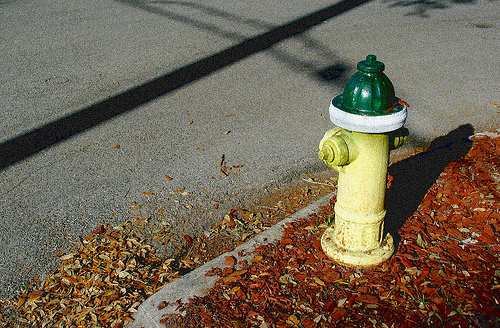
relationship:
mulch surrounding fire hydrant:
[0, 113, 500, 328] [310, 52, 416, 273]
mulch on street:
[4, 200, 260, 326] [7, 30, 309, 245]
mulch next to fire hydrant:
[0, 113, 500, 328] [310, 52, 416, 273]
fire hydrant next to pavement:
[303, 42, 409, 272] [0, 1, 500, 328]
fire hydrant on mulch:
[317, 55, 409, 270] [404, 134, 498, 326]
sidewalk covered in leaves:
[17, 15, 482, 304] [24, 134, 493, 327]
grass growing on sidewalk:
[413, 290, 431, 310] [125, 123, 497, 326]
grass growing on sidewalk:
[441, 296, 453, 307] [125, 123, 497, 326]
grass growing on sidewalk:
[325, 211, 334, 225] [125, 123, 497, 326]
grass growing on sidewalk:
[312, 214, 320, 231] [125, 123, 497, 326]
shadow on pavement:
[376, 0, 473, 21] [101, 72, 218, 93]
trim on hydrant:
[327, 99, 407, 134] [288, 61, 468, 295]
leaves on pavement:
[0, 222, 193, 328] [2, 2, 499, 204]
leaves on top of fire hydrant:
[384, 93, 414, 114] [306, 54, 433, 286]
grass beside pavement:
[412, 285, 427, 310] [0, 1, 500, 328]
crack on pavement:
[0, 145, 89, 197] [0, 1, 499, 326]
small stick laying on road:
[295, 174, 341, 196] [189, 76, 304, 166]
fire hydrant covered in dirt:
[317, 55, 409, 270] [201, 270, 498, 323]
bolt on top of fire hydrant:
[364, 53, 376, 66] [317, 55, 409, 270]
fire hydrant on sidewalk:
[317, 55, 409, 270] [125, 123, 497, 326]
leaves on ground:
[3, 211, 179, 326] [2, 1, 497, 323]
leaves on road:
[221, 155, 231, 175] [2, 0, 498, 325]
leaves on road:
[86, 223, 104, 240] [2, 0, 498, 325]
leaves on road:
[181, 234, 193, 244] [2, 0, 498, 325]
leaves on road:
[301, 175, 327, 186] [2, 0, 498, 325]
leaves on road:
[55, 250, 77, 265] [2, 0, 498, 325]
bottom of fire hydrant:
[316, 202, 395, 269] [296, 37, 427, 301]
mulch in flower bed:
[0, 113, 500, 328] [395, 162, 492, 314]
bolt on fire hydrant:
[388, 130, 409, 150] [317, 55, 409, 270]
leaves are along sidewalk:
[8, 221, 204, 326] [125, 123, 497, 326]